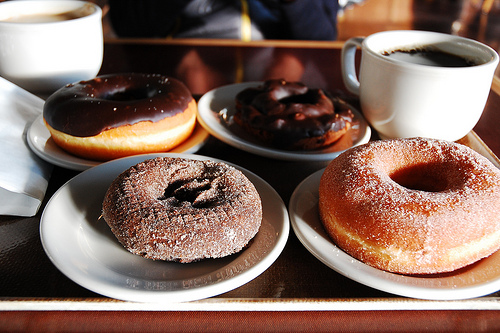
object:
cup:
[340, 29, 498, 141]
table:
[0, 93, 499, 332]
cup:
[0, 0, 105, 89]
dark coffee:
[381, 42, 481, 66]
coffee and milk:
[0, 13, 478, 70]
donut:
[101, 156, 264, 262]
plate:
[37, 152, 291, 302]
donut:
[318, 137, 499, 274]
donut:
[45, 72, 197, 160]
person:
[105, 0, 341, 95]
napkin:
[1, 76, 52, 217]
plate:
[290, 167, 500, 301]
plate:
[27, 115, 208, 170]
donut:
[233, 78, 355, 151]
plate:
[197, 80, 371, 161]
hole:
[390, 162, 454, 194]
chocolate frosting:
[42, 73, 191, 138]